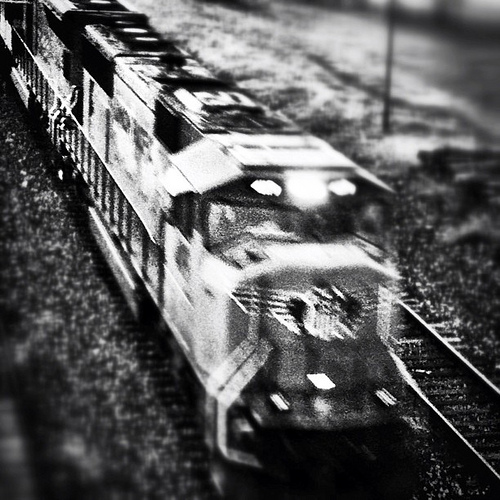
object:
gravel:
[1, 103, 226, 498]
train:
[2, 155, 63, 390]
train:
[6, 2, 399, 494]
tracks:
[399, 307, 498, 488]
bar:
[203, 339, 268, 467]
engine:
[227, 258, 390, 350]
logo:
[301, 288, 348, 340]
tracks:
[144, 358, 207, 497]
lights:
[254, 179, 281, 198]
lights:
[331, 181, 354, 198]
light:
[291, 180, 327, 209]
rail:
[46, 154, 121, 288]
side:
[80, 76, 151, 276]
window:
[209, 200, 309, 245]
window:
[306, 202, 384, 247]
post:
[386, 4, 388, 136]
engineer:
[349, 212, 370, 235]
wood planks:
[409, 352, 453, 377]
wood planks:
[393, 326, 424, 337]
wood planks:
[399, 335, 431, 346]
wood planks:
[443, 400, 496, 410]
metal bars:
[51, 110, 64, 151]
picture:
[3, 4, 500, 499]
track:
[163, 370, 220, 493]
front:
[215, 240, 398, 418]